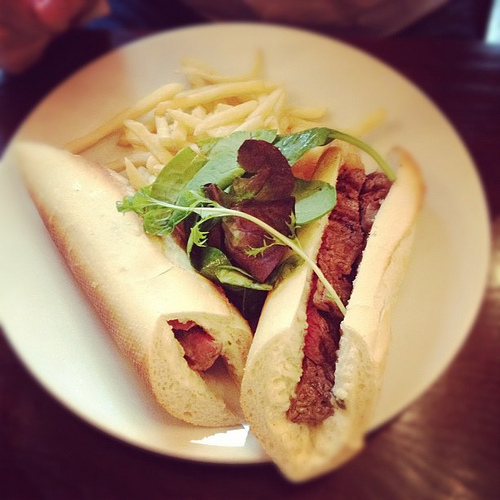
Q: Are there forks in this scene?
A: No, there are no forks.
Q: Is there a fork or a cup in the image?
A: No, there are no forks or cups.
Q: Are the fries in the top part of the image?
A: Yes, the fries are in the top of the image.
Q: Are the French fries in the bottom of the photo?
A: No, the French fries are in the top of the image.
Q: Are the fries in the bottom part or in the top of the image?
A: The fries are in the top of the image.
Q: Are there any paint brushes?
A: No, there are no paint brushes.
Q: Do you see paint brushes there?
A: No, there are no paint brushes.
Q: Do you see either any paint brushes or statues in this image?
A: No, there are no paint brushes or statues.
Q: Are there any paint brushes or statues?
A: No, there are no paint brushes or statues.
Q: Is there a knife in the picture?
A: No, there are no knives.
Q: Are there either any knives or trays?
A: No, there are no knives or trays.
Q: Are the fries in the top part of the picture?
A: Yes, the fries are in the top of the image.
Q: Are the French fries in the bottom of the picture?
A: No, the French fries are in the top of the image.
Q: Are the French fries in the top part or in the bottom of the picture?
A: The French fries are in the top of the image.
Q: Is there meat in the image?
A: Yes, there is meat.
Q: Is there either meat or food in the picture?
A: Yes, there is meat.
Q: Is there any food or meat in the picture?
A: Yes, there is meat.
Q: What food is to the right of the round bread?
A: The food is meat.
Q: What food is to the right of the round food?
A: The food is meat.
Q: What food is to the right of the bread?
A: The food is meat.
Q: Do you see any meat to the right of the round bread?
A: Yes, there is meat to the right of the bread.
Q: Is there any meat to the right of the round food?
A: Yes, there is meat to the right of the bread.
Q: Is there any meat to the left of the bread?
A: No, the meat is to the right of the bread.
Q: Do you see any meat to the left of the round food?
A: No, the meat is to the right of the bread.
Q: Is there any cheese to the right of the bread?
A: No, there is meat to the right of the bread.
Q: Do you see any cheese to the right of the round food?
A: No, there is meat to the right of the bread.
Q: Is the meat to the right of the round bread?
A: Yes, the meat is to the right of the bread.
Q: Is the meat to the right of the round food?
A: Yes, the meat is to the right of the bread.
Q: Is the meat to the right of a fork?
A: No, the meat is to the right of the bread.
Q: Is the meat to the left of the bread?
A: No, the meat is to the right of the bread.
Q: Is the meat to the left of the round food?
A: No, the meat is to the right of the bread.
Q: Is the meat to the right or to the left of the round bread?
A: The meat is to the right of the bread.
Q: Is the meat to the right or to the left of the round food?
A: The meat is to the right of the bread.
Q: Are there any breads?
A: Yes, there is a bread.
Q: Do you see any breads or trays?
A: Yes, there is a bread.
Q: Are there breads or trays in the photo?
A: Yes, there is a bread.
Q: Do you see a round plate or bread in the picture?
A: Yes, there is a round bread.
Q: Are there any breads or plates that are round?
A: Yes, the bread is round.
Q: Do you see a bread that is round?
A: Yes, there is a round bread.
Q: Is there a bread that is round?
A: Yes, there is a bread that is round.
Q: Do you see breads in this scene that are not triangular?
A: Yes, there is a round bread.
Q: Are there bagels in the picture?
A: No, there are no bagels.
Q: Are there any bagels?
A: No, there are no bagels.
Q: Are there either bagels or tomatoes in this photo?
A: No, there are no bagels or tomatoes.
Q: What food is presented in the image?
A: The food is a bread.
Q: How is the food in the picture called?
A: The food is a bread.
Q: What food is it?
A: The food is a bread.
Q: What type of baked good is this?
A: This is a bread.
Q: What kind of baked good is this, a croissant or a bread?
A: This is a bread.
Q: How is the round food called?
A: The food is a bread.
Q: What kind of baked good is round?
A: The baked good is a bread.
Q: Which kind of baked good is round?
A: The baked good is a bread.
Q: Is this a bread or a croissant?
A: This is a bread.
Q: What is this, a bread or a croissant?
A: This is a bread.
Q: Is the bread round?
A: Yes, the bread is round.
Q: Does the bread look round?
A: Yes, the bread is round.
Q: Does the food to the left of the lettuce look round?
A: Yes, the bread is round.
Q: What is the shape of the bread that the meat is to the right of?
A: The bread is round.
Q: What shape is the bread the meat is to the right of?
A: The bread is round.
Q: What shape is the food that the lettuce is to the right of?
A: The bread is round.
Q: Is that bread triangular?
A: No, the bread is round.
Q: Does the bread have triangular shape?
A: No, the bread is round.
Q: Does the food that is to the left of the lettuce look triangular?
A: No, the bread is round.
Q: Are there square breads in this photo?
A: No, there is a bread but it is round.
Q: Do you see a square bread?
A: No, there is a bread but it is round.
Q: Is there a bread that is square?
A: No, there is a bread but it is round.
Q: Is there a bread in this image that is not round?
A: No, there is a bread but it is round.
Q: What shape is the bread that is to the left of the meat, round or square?
A: The bread is round.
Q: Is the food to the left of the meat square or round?
A: The bread is round.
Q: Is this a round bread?
A: Yes, this is a round bread.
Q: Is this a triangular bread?
A: No, this is a round bread.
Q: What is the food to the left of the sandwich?
A: The food is a bread.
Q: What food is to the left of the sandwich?
A: The food is a bread.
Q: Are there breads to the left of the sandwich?
A: Yes, there is a bread to the left of the sandwich.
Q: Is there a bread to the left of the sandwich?
A: Yes, there is a bread to the left of the sandwich.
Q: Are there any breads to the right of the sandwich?
A: No, the bread is to the left of the sandwich.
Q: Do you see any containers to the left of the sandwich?
A: No, there is a bread to the left of the sandwich.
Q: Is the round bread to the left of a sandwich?
A: Yes, the bread is to the left of a sandwich.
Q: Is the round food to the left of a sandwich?
A: Yes, the bread is to the left of a sandwich.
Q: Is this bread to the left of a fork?
A: No, the bread is to the left of a sandwich.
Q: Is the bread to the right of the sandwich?
A: No, the bread is to the left of the sandwich.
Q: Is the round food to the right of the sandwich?
A: No, the bread is to the left of the sandwich.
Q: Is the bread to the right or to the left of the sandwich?
A: The bread is to the left of the sandwich.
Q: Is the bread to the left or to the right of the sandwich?
A: The bread is to the left of the sandwich.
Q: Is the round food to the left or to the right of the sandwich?
A: The bread is to the left of the sandwich.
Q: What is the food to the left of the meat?
A: The food is a bread.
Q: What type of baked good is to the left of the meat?
A: The food is a bread.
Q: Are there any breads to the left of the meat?
A: Yes, there is a bread to the left of the meat.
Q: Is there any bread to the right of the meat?
A: No, the bread is to the left of the meat.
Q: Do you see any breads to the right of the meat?
A: No, the bread is to the left of the meat.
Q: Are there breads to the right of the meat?
A: No, the bread is to the left of the meat.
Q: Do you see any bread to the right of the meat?
A: No, the bread is to the left of the meat.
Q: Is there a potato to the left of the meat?
A: No, there is a bread to the left of the meat.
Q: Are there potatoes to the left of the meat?
A: No, there is a bread to the left of the meat.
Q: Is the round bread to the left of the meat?
A: Yes, the bread is to the left of the meat.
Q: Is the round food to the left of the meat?
A: Yes, the bread is to the left of the meat.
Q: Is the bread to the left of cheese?
A: No, the bread is to the left of the meat.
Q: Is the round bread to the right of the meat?
A: No, the bread is to the left of the meat.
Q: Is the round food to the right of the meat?
A: No, the bread is to the left of the meat.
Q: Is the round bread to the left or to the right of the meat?
A: The bread is to the left of the meat.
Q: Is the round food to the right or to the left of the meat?
A: The bread is to the left of the meat.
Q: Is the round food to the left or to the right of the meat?
A: The bread is to the left of the meat.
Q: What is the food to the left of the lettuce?
A: The food is a bread.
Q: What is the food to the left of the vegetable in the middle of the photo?
A: The food is a bread.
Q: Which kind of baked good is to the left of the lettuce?
A: The food is a bread.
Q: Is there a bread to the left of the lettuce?
A: Yes, there is a bread to the left of the lettuce.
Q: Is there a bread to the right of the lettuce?
A: No, the bread is to the left of the lettuce.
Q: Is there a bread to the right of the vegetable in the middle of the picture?
A: No, the bread is to the left of the lettuce.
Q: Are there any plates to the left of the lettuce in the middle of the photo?
A: No, there is a bread to the left of the lettuce.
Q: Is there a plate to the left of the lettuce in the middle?
A: No, there is a bread to the left of the lettuce.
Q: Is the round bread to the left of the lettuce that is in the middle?
A: Yes, the bread is to the left of the lettuce.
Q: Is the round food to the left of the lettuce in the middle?
A: Yes, the bread is to the left of the lettuce.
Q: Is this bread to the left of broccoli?
A: No, the bread is to the left of the lettuce.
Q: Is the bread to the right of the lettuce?
A: No, the bread is to the left of the lettuce.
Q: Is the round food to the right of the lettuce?
A: No, the bread is to the left of the lettuce.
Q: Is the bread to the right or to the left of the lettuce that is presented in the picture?
A: The bread is to the left of the lettuce.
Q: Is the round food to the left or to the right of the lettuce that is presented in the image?
A: The bread is to the left of the lettuce.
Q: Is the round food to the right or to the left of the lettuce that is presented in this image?
A: The bread is to the left of the lettuce.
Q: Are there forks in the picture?
A: No, there are no forks.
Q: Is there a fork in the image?
A: No, there are no forks.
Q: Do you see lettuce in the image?
A: Yes, there is lettuce.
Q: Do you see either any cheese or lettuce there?
A: Yes, there is lettuce.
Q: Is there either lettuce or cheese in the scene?
A: Yes, there is lettuce.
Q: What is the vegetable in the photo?
A: The vegetable is lettuce.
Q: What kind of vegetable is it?
A: The vegetable is lettuce.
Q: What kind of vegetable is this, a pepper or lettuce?
A: This is lettuce.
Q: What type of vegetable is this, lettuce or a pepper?
A: This is lettuce.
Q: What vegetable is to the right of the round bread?
A: The vegetable is lettuce.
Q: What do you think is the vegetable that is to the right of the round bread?
A: The vegetable is lettuce.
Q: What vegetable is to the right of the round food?
A: The vegetable is lettuce.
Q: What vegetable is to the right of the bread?
A: The vegetable is lettuce.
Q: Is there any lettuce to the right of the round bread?
A: Yes, there is lettuce to the right of the bread.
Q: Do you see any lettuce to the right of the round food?
A: Yes, there is lettuce to the right of the bread.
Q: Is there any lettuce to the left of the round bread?
A: No, the lettuce is to the right of the bread.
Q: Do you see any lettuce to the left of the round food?
A: No, the lettuce is to the right of the bread.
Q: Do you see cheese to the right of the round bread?
A: No, there is lettuce to the right of the bread.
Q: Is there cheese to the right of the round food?
A: No, there is lettuce to the right of the bread.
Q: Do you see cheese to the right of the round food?
A: No, there is lettuce to the right of the bread.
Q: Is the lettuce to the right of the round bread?
A: Yes, the lettuce is to the right of the bread.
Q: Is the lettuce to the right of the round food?
A: Yes, the lettuce is to the right of the bread.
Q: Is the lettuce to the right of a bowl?
A: No, the lettuce is to the right of the bread.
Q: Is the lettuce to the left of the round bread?
A: No, the lettuce is to the right of the bread.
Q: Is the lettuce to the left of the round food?
A: No, the lettuce is to the right of the bread.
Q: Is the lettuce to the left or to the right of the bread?
A: The lettuce is to the right of the bread.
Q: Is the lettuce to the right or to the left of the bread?
A: The lettuce is to the right of the bread.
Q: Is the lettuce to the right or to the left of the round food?
A: The lettuce is to the right of the bread.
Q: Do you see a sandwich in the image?
A: Yes, there is a sandwich.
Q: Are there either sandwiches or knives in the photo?
A: Yes, there is a sandwich.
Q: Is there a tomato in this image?
A: No, there are no tomatoes.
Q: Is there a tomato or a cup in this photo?
A: No, there are no tomatoes or cups.